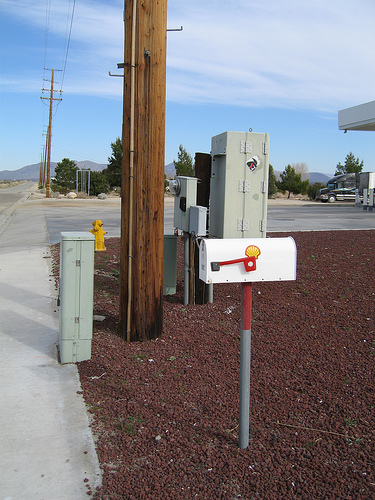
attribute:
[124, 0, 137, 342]
lining — tan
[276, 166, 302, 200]
tree — small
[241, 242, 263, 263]
symbol — yellow and red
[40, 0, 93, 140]
wires — electrical 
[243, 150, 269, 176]
sticker — black and white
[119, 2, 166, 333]
pole — wooden and electrical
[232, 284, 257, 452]
pole — red and gray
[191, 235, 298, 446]
mailbox — white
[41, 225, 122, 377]
box — small, green, electric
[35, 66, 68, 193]
poles — brown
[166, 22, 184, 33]
hook — metal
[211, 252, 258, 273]
flag — red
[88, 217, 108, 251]
hydrant — yellow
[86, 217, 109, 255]
hydrant — yellow 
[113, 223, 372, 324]
gravel — red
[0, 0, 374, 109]
cloud — high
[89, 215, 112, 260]
hydrant — yellow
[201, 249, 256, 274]
flag — red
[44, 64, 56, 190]
power pole — tall and brown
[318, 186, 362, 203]
car — black and white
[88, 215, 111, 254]
fire hydrant — yellow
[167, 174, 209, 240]
electric meter — grey, tall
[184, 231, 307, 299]
mailbox — white and metal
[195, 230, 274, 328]
stake — metal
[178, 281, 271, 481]
pole — gray and red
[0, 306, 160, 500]
gravel — brown